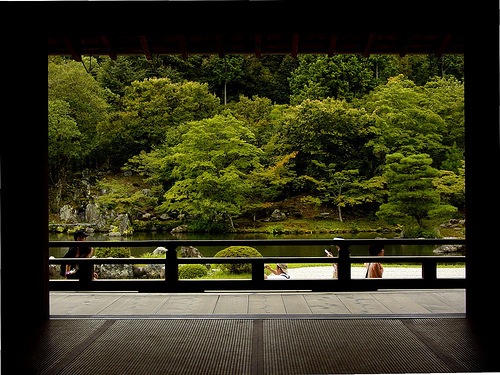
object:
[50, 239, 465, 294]
rail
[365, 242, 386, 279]
woman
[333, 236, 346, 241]
hat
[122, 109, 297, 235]
tree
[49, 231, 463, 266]
pond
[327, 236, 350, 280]
man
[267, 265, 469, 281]
sand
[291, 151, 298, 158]
leaf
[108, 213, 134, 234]
rock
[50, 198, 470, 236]
shore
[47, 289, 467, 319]
walkway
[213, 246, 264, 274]
bush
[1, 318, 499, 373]
carpet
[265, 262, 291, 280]
person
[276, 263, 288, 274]
head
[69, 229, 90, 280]
person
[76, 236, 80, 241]
ear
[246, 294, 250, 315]
crack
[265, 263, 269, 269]
camera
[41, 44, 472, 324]
door